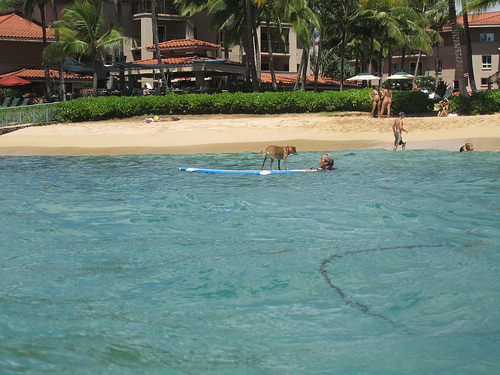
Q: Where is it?
A: This is at the ocean.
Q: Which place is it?
A: It is an ocean.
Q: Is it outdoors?
A: Yes, it is outdoors.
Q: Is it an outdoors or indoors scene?
A: It is outdoors.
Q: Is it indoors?
A: No, it is outdoors.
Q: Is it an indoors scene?
A: No, it is outdoors.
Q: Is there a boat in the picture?
A: No, there are no boats.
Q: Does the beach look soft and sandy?
A: Yes, the beach is soft and sandy.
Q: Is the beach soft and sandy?
A: Yes, the beach is soft and sandy.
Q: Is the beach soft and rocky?
A: No, the beach is soft but sandy.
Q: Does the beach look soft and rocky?
A: No, the beach is soft but sandy.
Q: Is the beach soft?
A: Yes, the beach is soft.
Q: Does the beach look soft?
A: Yes, the beach is soft.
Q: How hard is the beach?
A: The beach is soft.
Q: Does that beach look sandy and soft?
A: Yes, the beach is sandy and soft.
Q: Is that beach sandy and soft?
A: Yes, the beach is sandy and soft.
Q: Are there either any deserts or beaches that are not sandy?
A: No, there is a beach but it is sandy.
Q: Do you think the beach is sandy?
A: Yes, the beach is sandy.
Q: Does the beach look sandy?
A: Yes, the beach is sandy.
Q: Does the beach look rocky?
A: No, the beach is sandy.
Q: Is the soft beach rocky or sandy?
A: The beach is sandy.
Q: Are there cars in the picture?
A: No, there are no cars.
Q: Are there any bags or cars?
A: No, there are no cars or bags.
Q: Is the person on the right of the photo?
A: Yes, the person is on the right of the image.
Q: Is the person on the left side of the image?
A: No, the person is on the right of the image.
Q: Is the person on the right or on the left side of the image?
A: The person is on the right of the image.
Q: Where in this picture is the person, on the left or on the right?
A: The person is on the right of the image.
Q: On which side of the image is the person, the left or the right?
A: The person is on the right of the image.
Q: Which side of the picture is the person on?
A: The person is on the right of the image.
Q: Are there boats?
A: No, there are no boats.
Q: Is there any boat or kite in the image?
A: No, there are no boats or kites.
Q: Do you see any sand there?
A: Yes, there is sand.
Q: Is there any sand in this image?
A: Yes, there is sand.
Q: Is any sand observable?
A: Yes, there is sand.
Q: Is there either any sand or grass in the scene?
A: Yes, there is sand.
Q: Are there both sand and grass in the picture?
A: No, there is sand but no grass.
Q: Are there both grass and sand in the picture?
A: No, there is sand but no grass.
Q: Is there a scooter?
A: No, there are no scooters.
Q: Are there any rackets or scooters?
A: No, there are no scooters or rackets.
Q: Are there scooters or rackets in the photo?
A: No, there are no scooters or rackets.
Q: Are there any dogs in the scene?
A: Yes, there is a dog.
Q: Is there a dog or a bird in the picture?
A: Yes, there is a dog.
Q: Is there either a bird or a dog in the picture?
A: Yes, there is a dog.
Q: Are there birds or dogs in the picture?
A: Yes, there is a dog.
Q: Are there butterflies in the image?
A: No, there are no butterflies.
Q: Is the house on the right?
A: Yes, the house is on the right of the image.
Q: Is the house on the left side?
A: No, the house is on the right of the image.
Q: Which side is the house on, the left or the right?
A: The house is on the right of the image.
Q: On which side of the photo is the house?
A: The house is on the right of the image.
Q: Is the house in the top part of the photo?
A: Yes, the house is in the top of the image.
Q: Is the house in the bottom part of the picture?
A: No, the house is in the top of the image.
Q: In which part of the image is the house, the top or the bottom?
A: The house is in the top of the image.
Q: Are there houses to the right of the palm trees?
A: Yes, there is a house to the right of the palm trees.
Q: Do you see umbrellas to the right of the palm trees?
A: No, there is a house to the right of the palm trees.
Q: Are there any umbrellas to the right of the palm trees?
A: No, there is a house to the right of the palm trees.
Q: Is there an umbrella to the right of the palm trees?
A: No, there is a house to the right of the palm trees.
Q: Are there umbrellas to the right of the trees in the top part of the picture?
A: No, there is a house to the right of the palm trees.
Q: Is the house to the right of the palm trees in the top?
A: Yes, the house is to the right of the palm trees.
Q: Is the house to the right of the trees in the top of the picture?
A: Yes, the house is to the right of the palm trees.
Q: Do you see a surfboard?
A: Yes, there is a surfboard.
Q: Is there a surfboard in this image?
A: Yes, there is a surfboard.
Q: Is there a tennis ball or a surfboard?
A: Yes, there is a surfboard.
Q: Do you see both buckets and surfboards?
A: No, there is a surfboard but no buckets.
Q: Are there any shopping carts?
A: No, there are no shopping carts.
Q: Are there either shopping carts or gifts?
A: No, there are no shopping carts or gifts.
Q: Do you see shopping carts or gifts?
A: No, there are no shopping carts or gifts.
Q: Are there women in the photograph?
A: Yes, there is a woman.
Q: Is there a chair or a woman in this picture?
A: Yes, there is a woman.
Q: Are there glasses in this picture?
A: No, there are no glasses.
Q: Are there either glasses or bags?
A: No, there are no glasses or bags.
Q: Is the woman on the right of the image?
A: Yes, the woman is on the right of the image.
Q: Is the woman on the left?
A: No, the woman is on the right of the image.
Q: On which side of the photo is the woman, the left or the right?
A: The woman is on the right of the image.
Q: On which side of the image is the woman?
A: The woman is on the right of the image.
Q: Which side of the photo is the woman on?
A: The woman is on the right of the image.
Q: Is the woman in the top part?
A: Yes, the woman is in the top of the image.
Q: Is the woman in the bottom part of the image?
A: No, the woman is in the top of the image.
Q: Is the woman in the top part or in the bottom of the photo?
A: The woman is in the top of the image.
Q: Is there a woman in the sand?
A: Yes, there is a woman in the sand.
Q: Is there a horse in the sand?
A: No, there is a woman in the sand.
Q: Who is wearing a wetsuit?
A: The woman is wearing a wetsuit.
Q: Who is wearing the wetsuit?
A: The woman is wearing a wetsuit.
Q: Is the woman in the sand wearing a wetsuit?
A: Yes, the woman is wearing a wetsuit.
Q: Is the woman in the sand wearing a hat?
A: No, the woman is wearing a wetsuit.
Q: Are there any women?
A: Yes, there is a woman.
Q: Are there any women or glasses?
A: Yes, there is a woman.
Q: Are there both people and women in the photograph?
A: Yes, there are both a woman and a person.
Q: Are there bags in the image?
A: No, there are no bags.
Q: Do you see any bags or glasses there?
A: No, there are no bags or glasses.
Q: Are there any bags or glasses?
A: No, there are no bags or glasses.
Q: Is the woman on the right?
A: Yes, the woman is on the right of the image.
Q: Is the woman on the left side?
A: No, the woman is on the right of the image.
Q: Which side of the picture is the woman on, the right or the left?
A: The woman is on the right of the image.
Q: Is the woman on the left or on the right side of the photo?
A: The woman is on the right of the image.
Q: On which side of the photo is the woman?
A: The woman is on the right of the image.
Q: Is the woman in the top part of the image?
A: Yes, the woman is in the top of the image.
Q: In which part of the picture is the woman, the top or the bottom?
A: The woman is in the top of the image.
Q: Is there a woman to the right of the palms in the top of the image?
A: Yes, there is a woman to the right of the palm trees.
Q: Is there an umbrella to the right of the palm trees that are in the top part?
A: No, there is a woman to the right of the palm trees.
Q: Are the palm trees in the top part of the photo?
A: Yes, the palm trees are in the top of the image.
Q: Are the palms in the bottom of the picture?
A: No, the palms are in the top of the image.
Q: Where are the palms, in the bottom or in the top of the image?
A: The palms are in the top of the image.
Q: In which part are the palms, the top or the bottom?
A: The palms are in the top of the image.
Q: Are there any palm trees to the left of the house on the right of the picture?
A: Yes, there are palm trees to the left of the house.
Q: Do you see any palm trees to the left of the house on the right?
A: Yes, there are palm trees to the left of the house.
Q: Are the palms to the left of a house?
A: Yes, the palms are to the left of a house.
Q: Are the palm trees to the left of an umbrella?
A: No, the palm trees are to the left of a house.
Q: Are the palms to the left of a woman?
A: Yes, the palms are to the left of a woman.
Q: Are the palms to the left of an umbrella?
A: No, the palms are to the left of a woman.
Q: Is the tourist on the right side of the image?
A: Yes, the tourist is on the right of the image.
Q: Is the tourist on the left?
A: No, the tourist is on the right of the image.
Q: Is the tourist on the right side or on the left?
A: The tourist is on the right of the image.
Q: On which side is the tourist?
A: The tourist is on the right of the image.